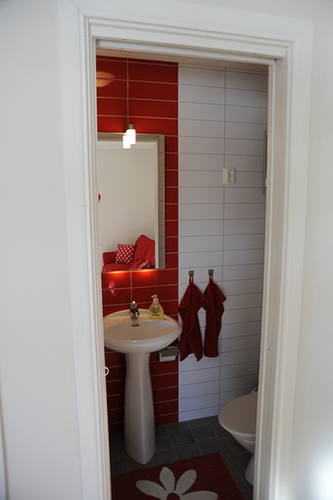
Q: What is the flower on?
A: Rug.